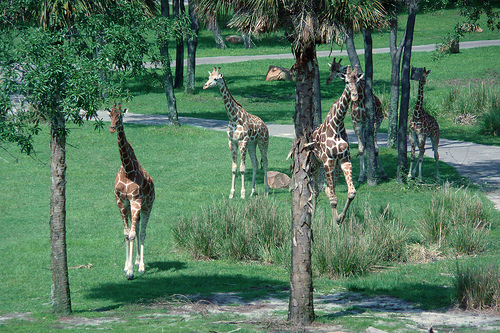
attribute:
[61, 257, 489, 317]
shadow — dark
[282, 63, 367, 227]
giraffe — brown , white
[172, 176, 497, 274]
bushes — small 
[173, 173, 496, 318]
bushes — small 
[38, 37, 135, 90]
leaves — green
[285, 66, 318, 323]
tree trunk — brown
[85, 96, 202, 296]
giraffe — brown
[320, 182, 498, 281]
tall grass — green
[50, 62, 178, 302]
giraffe — brown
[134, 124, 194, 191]
lawn — green 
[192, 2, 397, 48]
leaves — drying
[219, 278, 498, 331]
patches — Dirt 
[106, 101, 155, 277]
giraffe — brown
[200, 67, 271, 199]
giraffe — brown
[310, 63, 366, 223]
giraffe — brown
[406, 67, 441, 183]
giraffe — brown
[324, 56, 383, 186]
giraffe — brown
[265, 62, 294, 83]
rock — grey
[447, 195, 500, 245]
bushes — small 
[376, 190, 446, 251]
bushes — small